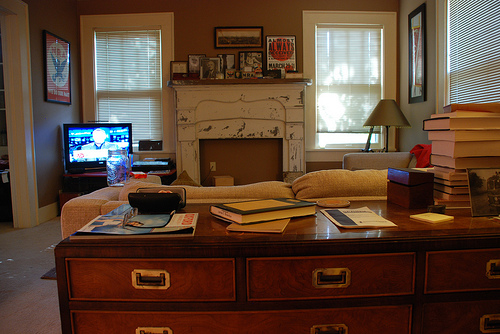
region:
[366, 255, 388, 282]
part of a drawer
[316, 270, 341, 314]
part of a andle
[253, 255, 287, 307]
part of a board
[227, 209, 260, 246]
edge of a board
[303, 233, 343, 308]
part of a frawer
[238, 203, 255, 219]
edge of a book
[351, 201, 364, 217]
part of a paoer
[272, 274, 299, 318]
part of a board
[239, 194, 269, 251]
part o fa book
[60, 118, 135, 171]
black tv that's on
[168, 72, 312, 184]
white faded fireplace with no fire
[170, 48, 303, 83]
pictures on the fireplace mantle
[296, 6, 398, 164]
window with large white frame and blinds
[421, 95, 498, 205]
pile of books on the table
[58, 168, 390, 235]
beige fabric couch behind the table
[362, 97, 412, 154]
gray and black lamp behind the couch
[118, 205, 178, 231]
clear and black glasses on the magazine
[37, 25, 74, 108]
picture on the wall with thin black frame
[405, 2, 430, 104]
picture on the wall with thick black frame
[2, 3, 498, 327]
A living room scene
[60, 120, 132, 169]
The television is on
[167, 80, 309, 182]
A fireplace is in the wall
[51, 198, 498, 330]
A chest of drawers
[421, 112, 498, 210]
Books are stacked on the chest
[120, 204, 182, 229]
A pair of eyeglasses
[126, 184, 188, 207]
An eyeglass case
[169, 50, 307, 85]
Photos and knickknacks are on the mantel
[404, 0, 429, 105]
A framed painting is on the wall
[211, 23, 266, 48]
A framed photograph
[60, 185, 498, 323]
dresser behind white couch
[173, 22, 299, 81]
picture frames on white mantle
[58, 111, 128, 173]
television next to window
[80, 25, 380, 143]
two windows in living room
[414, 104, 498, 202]
stack of books on dresser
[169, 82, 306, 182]
white fireplace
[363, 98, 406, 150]
lamp sitting by window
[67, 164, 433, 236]
white couch in living room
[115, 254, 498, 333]
handles on brown dresser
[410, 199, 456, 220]
yellow sticky pad on top of dresser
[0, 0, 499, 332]
living room with large dresser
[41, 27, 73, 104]
framed NRA poster on left wall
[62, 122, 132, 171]
television tuned in to news channel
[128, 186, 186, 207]
hard black case for reading glasses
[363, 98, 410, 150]
table lamp next to window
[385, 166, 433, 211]
wood box to hold index cards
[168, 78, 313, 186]
mantle with peeling paint over inoperable fireplace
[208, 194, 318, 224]
black and yellow hard cover book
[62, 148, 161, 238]
clear glass mason jar on arm of couch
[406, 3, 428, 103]
black framed picture on right wall